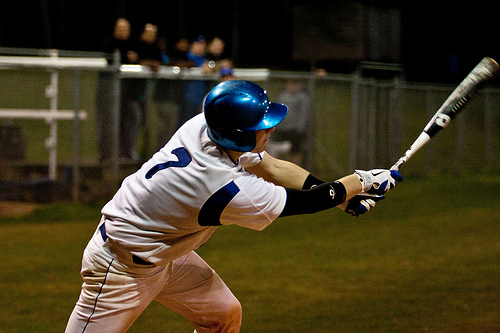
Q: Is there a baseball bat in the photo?
A: Yes, there is a baseball bat.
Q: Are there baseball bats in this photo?
A: Yes, there is a baseball bat.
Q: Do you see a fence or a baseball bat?
A: Yes, there is a baseball bat.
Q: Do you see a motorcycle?
A: No, there are no motorcycles.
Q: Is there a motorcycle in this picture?
A: No, there are no motorcycles.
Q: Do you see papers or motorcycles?
A: No, there are no motorcycles or papers.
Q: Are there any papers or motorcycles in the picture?
A: No, there are no motorcycles or papers.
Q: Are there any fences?
A: Yes, there is a fence.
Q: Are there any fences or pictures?
A: Yes, there is a fence.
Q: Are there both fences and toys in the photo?
A: No, there is a fence but no toys.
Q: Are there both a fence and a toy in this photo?
A: No, there is a fence but no toys.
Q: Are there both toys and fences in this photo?
A: No, there is a fence but no toys.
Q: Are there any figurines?
A: No, there are no figurines.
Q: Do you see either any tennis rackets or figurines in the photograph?
A: No, there are no figurines or tennis rackets.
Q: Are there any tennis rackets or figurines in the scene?
A: No, there are no figurines or tennis rackets.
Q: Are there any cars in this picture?
A: No, there are no cars.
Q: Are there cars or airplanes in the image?
A: No, there are no cars or airplanes.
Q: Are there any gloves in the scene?
A: Yes, there are gloves.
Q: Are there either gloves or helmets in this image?
A: Yes, there are gloves.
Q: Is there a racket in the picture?
A: No, there are no rackets.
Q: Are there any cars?
A: No, there are no cars.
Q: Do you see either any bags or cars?
A: No, there are no cars or bags.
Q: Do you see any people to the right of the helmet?
A: Yes, there is a person to the right of the helmet.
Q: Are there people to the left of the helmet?
A: No, the person is to the right of the helmet.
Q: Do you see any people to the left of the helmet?
A: No, the person is to the right of the helmet.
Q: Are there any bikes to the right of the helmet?
A: No, there is a person to the right of the helmet.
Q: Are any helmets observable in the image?
A: Yes, there is a helmet.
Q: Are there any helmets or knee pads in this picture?
A: Yes, there is a helmet.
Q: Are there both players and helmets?
A: Yes, there are both a helmet and a player.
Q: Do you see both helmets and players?
A: Yes, there are both a helmet and a player.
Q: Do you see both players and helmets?
A: Yes, there are both a helmet and a player.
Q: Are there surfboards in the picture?
A: No, there are no surfboards.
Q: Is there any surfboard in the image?
A: No, there are no surfboards.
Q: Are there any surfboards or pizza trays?
A: No, there are no surfboards or pizza trays.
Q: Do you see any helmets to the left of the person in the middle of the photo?
A: Yes, there is a helmet to the left of the person.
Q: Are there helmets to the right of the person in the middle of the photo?
A: No, the helmet is to the left of the person.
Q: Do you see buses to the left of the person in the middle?
A: No, there is a helmet to the left of the person.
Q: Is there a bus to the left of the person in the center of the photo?
A: No, there is a helmet to the left of the person.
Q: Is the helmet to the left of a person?
A: Yes, the helmet is to the left of a person.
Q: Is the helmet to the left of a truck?
A: No, the helmet is to the left of a person.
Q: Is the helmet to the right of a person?
A: No, the helmet is to the left of a person.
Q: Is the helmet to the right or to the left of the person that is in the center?
A: The helmet is to the left of the person.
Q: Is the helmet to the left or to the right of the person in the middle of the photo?
A: The helmet is to the left of the person.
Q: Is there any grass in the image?
A: Yes, there is grass.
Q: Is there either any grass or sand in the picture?
A: Yes, there is grass.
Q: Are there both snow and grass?
A: No, there is grass but no snow.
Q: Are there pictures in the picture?
A: No, there are no pictures.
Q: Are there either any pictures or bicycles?
A: No, there are no pictures or bicycles.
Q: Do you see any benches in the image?
A: No, there are no benches.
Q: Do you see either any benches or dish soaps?
A: No, there are no benches or dish soaps.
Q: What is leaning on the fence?
A: The fans are leaning on the fence.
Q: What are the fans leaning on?
A: The fans are leaning on the fence.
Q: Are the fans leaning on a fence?
A: Yes, the fans are leaning on a fence.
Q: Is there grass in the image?
A: Yes, there is grass.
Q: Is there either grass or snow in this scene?
A: Yes, there is grass.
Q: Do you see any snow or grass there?
A: Yes, there is grass.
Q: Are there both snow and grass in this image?
A: No, there is grass but no snow.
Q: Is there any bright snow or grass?
A: Yes, there is bright grass.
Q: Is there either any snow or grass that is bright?
A: Yes, the grass is bright.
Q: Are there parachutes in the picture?
A: No, there are no parachutes.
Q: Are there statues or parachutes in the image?
A: No, there are no parachutes or statues.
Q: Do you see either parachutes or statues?
A: No, there are no parachutes or statues.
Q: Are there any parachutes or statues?
A: No, there are no parachutes or statues.